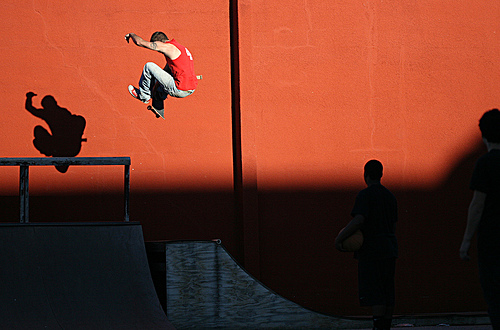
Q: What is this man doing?
A: This man is doing tricks.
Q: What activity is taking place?
A: Skateboarding.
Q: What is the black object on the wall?
A: Shadow.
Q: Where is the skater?
A: In the air.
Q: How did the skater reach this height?
A: Ramp.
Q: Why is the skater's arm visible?
A: Sleeveless shirt.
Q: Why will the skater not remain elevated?
A: Gravity.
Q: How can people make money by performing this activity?
A: Become a professional.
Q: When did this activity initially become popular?
A: 1970s.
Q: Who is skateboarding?
A: The boy.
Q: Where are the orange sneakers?
A: Boy's feet.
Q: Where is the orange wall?
A: In front of man.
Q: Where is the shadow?
A: On wall.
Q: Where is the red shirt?
A: On man.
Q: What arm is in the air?
A: Left.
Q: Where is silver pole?
A: On left.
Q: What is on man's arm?
A: Tattoo.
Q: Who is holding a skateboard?
A: The man.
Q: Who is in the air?
A: Skateboarder.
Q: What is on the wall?
A: A shadow.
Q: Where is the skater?
A: At a skatepark.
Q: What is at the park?
A: A ramp.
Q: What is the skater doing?
A: A trick.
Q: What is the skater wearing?
A: A red shirt.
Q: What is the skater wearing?
A: Jeans.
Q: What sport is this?
A: Skateboarding.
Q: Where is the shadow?
A: On the wall.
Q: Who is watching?
A: A couple of other guys.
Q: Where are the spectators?
A: Behind the skater.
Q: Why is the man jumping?
A: He is doing a trick.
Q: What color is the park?
A: Red.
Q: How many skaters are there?
A: Three.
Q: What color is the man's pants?
A: Grey.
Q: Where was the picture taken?
A: The skate park.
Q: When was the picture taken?
A: Afternoon.